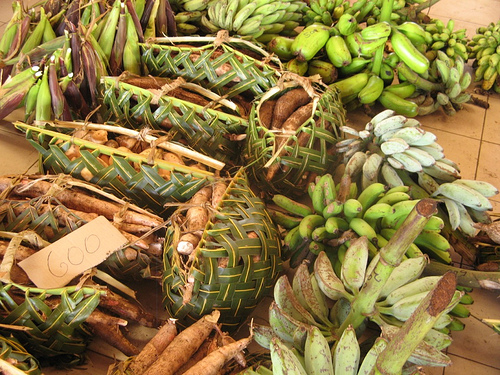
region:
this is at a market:
[30, 35, 448, 357]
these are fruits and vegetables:
[22, 40, 408, 327]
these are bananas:
[288, 193, 440, 274]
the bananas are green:
[283, 180, 473, 277]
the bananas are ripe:
[297, 165, 436, 252]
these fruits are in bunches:
[295, 169, 475, 374]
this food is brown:
[159, 182, 238, 275]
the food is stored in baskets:
[130, 36, 301, 164]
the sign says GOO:
[32, 227, 154, 296]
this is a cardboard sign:
[10, 222, 144, 285]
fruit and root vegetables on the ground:
[15, 0, 462, 357]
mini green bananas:
[287, 11, 497, 371]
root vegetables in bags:
[12, 25, 312, 368]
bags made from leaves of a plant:
[160, 160, 277, 326]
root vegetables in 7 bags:
[11, 27, 316, 317]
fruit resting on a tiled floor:
[1, 1, 486, 369]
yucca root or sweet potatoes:
[102, 316, 252, 370]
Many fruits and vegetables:
[8, 8, 490, 362]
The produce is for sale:
[15, 4, 499, 359]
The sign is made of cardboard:
[25, 218, 132, 282]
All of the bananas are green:
[281, 173, 436, 254]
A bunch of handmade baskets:
[66, 53, 331, 311]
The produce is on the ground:
[12, 5, 485, 357]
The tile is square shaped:
[451, 114, 496, 168]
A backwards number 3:
[369, 258, 386, 285]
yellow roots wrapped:
[1, 28, 345, 373]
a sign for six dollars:
[16, 214, 126, 290]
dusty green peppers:
[255, 203, 452, 373]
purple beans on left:
[1, 1, 183, 121]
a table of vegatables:
[1, 0, 498, 373]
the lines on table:
[468, 95, 495, 183]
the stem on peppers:
[345, 192, 456, 374]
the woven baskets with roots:
[9, 23, 351, 333]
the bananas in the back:
[172, 6, 460, 120]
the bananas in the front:
[286, 129, 450, 374]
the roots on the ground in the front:
[133, 297, 251, 374]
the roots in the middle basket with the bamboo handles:
[40, 115, 236, 207]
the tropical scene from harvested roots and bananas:
[15, 11, 480, 363]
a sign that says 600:
[43, 220, 113, 283]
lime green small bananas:
[298, 183, 432, 233]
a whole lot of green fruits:
[0, 8, 496, 329]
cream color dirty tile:
[449, 124, 490, 162]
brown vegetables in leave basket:
[238, 93, 335, 152]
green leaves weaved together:
[226, 221, 270, 273]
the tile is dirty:
[462, 123, 490, 151]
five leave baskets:
[37, 43, 301, 235]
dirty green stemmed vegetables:
[283, 251, 420, 367]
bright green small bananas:
[462, 19, 498, 91]